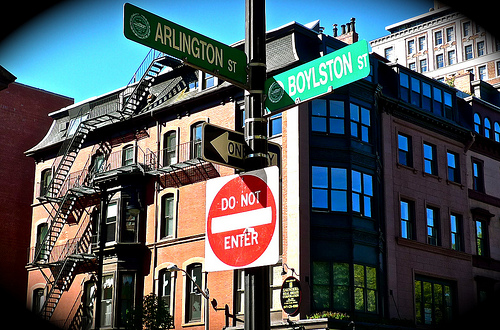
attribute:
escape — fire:
[27, 92, 129, 327]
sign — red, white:
[200, 159, 287, 274]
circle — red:
[204, 174, 275, 270]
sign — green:
[269, 39, 373, 120]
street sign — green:
[260, 33, 375, 129]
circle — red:
[206, 176, 277, 266]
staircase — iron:
[31, 50, 177, 328]